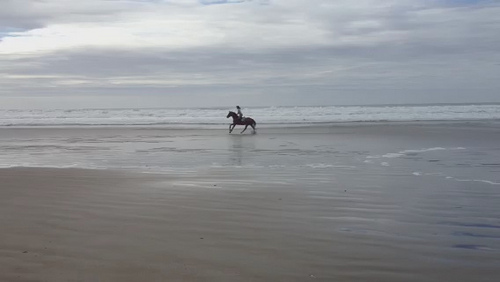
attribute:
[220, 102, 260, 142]
horse — brown 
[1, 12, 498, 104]
sky — blue 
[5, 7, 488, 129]
sky — blue 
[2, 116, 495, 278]
beach — sandy, empty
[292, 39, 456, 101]
sky — blue 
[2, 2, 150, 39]
cloud — white 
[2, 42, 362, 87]
cloud — white 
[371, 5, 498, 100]
cloud — white 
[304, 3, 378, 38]
cloud — white 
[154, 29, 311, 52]
sky — blue 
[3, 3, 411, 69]
cloud — white 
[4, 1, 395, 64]
cloud — white 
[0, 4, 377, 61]
cloud — white 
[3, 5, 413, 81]
cloud — white 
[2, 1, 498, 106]
sky — blue 